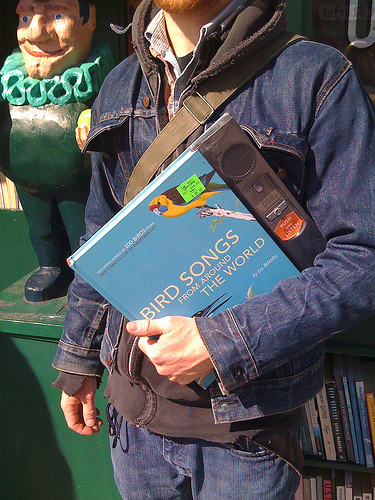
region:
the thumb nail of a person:
[125, 317, 141, 336]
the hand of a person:
[125, 306, 224, 391]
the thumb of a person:
[124, 309, 177, 339]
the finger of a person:
[61, 401, 95, 439]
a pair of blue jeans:
[98, 395, 305, 498]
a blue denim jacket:
[43, 16, 368, 426]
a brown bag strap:
[118, 27, 306, 211]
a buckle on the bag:
[178, 86, 216, 125]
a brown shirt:
[46, 305, 301, 453]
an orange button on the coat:
[137, 91, 153, 110]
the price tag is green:
[180, 177, 208, 200]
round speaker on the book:
[221, 142, 258, 183]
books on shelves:
[274, 379, 374, 497]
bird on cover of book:
[140, 169, 233, 216]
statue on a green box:
[10, 21, 73, 445]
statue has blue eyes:
[11, 9, 71, 27]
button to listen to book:
[268, 203, 286, 219]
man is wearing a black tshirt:
[169, 43, 197, 70]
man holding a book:
[115, 133, 371, 358]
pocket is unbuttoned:
[84, 119, 127, 158]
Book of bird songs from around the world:
[65, 126, 299, 325]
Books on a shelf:
[314, 379, 370, 462]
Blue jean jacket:
[48, 13, 369, 413]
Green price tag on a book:
[173, 172, 206, 202]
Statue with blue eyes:
[5, 1, 98, 301]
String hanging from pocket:
[102, 395, 127, 451]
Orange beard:
[149, 0, 219, 19]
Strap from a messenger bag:
[123, 45, 261, 199]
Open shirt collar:
[139, 15, 181, 84]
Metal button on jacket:
[139, 92, 154, 115]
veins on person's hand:
[169, 352, 208, 375]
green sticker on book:
[156, 177, 212, 213]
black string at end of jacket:
[96, 399, 130, 446]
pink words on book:
[148, 244, 265, 299]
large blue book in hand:
[51, 162, 334, 357]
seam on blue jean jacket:
[165, 302, 271, 401]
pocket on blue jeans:
[221, 430, 298, 469]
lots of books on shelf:
[310, 383, 365, 464]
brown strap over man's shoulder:
[88, 77, 234, 175]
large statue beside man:
[11, 13, 97, 211]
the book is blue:
[64, 234, 250, 413]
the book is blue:
[57, 137, 331, 418]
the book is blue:
[90, 177, 308, 350]